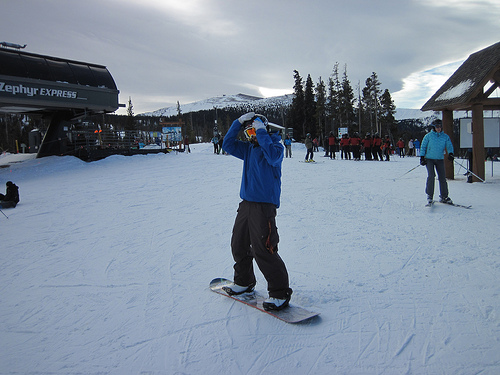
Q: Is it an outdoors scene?
A: Yes, it is outdoors.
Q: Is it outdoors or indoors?
A: It is outdoors.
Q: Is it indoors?
A: No, it is outdoors.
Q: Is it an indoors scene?
A: No, it is outdoors.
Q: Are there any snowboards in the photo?
A: Yes, there is a snowboard.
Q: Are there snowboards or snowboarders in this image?
A: Yes, there is a snowboard.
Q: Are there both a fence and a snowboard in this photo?
A: No, there is a snowboard but no fences.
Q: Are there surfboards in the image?
A: No, there are no surfboards.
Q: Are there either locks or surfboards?
A: No, there are no surfboards or locks.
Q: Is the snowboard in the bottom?
A: Yes, the snowboard is in the bottom of the image.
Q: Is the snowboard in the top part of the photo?
A: No, the snowboard is in the bottom of the image.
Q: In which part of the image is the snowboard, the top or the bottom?
A: The snowboard is in the bottom of the image.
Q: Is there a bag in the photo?
A: No, there are no bags.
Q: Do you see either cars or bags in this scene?
A: No, there are no bags or cars.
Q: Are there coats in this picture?
A: Yes, there is a coat.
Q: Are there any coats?
A: Yes, there is a coat.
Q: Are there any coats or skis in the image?
A: Yes, there is a coat.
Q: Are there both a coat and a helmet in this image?
A: Yes, there are both a coat and a helmet.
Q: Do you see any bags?
A: No, there are no bags.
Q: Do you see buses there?
A: Yes, there is a bus.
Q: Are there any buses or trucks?
A: Yes, there is a bus.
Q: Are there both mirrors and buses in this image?
A: No, there is a bus but no mirrors.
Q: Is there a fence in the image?
A: No, there are no fences.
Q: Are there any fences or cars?
A: No, there are no fences or cars.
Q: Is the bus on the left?
A: Yes, the bus is on the left of the image.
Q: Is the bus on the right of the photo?
A: No, the bus is on the left of the image.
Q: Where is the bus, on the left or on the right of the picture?
A: The bus is on the left of the image.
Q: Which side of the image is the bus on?
A: The bus is on the left of the image.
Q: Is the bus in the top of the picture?
A: Yes, the bus is in the top of the image.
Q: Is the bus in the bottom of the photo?
A: No, the bus is in the top of the image.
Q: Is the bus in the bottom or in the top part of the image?
A: The bus is in the top of the image.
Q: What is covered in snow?
A: The mountain is covered in snow.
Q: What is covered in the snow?
A: The mountain is covered in snow.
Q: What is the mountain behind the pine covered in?
A: The mountain is covered in snow.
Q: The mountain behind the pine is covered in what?
A: The mountain is covered in snow.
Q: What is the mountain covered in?
A: The mountain is covered in snow.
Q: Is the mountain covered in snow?
A: Yes, the mountain is covered in snow.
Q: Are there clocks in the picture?
A: No, there are no clocks.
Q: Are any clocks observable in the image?
A: No, there are no clocks.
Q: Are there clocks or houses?
A: No, there are no clocks or houses.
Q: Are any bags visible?
A: No, there are no bags.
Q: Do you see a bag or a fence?
A: No, there are no bags or fences.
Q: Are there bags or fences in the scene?
A: No, there are no bags or fences.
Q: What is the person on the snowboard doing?
A: The person is standing.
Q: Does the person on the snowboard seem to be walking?
A: No, the person is standing.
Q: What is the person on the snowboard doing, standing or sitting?
A: The person is standing.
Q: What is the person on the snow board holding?
A: The person is holding the helmet.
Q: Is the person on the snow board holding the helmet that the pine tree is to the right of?
A: Yes, the person is holding the helmet.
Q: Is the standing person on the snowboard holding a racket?
A: No, the person is holding the helmet.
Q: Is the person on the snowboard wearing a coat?
A: Yes, the person is wearing a coat.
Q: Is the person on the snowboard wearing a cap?
A: No, the person is wearing a coat.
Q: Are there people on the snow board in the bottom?
A: Yes, there is a person on the snow board.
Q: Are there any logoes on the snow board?
A: No, there is a person on the snow board.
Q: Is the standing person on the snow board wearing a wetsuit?
A: No, the person is wearing a helmet.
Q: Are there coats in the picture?
A: Yes, there is a coat.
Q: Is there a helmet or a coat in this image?
A: Yes, there is a coat.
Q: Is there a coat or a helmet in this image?
A: Yes, there is a coat.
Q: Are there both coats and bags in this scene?
A: No, there is a coat but no bags.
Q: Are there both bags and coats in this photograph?
A: No, there is a coat but no bags.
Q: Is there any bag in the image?
A: No, there are no bags.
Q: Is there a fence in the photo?
A: No, there are no fences.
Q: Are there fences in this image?
A: No, there are no fences.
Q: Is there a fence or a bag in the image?
A: No, there are no fences or bags.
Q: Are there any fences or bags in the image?
A: No, there are no fences or bags.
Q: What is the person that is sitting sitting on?
A: The person is sitting on the snow.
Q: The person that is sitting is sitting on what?
A: The person is sitting on the snow.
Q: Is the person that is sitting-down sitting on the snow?
A: Yes, the person is sitting on the snow.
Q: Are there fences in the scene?
A: No, there are no fences.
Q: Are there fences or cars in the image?
A: No, there are no fences or cars.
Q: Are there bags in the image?
A: No, there are no bags.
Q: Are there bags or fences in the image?
A: No, there are no bags or fences.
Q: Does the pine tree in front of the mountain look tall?
A: Yes, the pine is tall.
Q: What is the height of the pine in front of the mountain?
A: The pine tree is tall.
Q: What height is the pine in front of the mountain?
A: The pine tree is tall.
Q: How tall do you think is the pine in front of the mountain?
A: The pine tree is tall.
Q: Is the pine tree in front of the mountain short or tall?
A: The pine tree is tall.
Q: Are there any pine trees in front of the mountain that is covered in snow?
A: Yes, there is a pine tree in front of the mountain.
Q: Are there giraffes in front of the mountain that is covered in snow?
A: No, there is a pine tree in front of the mountain.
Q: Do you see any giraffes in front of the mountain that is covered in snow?
A: No, there is a pine tree in front of the mountain.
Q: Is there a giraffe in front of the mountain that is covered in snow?
A: No, there is a pine tree in front of the mountain.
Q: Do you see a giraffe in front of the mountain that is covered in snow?
A: No, there is a pine tree in front of the mountain.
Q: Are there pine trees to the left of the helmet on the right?
A: Yes, there is a pine tree to the left of the helmet.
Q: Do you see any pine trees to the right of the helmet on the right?
A: No, the pine tree is to the left of the helmet.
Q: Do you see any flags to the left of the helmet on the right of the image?
A: No, there is a pine tree to the left of the helmet.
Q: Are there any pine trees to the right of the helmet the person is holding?
A: Yes, there is a pine tree to the right of the helmet.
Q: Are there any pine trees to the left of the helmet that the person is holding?
A: No, the pine tree is to the right of the helmet.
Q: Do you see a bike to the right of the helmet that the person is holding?
A: No, there is a pine tree to the right of the helmet.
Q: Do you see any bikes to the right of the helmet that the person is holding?
A: No, there is a pine tree to the right of the helmet.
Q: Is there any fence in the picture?
A: No, there are no fences.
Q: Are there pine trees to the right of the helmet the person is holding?
A: Yes, there is a pine tree to the right of the helmet.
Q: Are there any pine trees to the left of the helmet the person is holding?
A: No, the pine tree is to the right of the helmet.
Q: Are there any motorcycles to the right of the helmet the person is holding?
A: No, there is a pine tree to the right of the helmet.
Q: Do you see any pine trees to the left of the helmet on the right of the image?
A: Yes, there is a pine tree to the left of the helmet.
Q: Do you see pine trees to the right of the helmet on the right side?
A: No, the pine tree is to the left of the helmet.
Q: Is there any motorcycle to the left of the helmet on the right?
A: No, there is a pine tree to the left of the helmet.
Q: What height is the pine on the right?
A: The pine tree is tall.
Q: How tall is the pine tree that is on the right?
A: The pine tree is tall.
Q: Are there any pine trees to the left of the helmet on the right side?
A: Yes, there is a pine tree to the left of the helmet.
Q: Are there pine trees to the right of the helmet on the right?
A: No, the pine tree is to the left of the helmet.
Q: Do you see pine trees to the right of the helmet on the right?
A: No, the pine tree is to the left of the helmet.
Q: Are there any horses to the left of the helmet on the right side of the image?
A: No, there is a pine tree to the left of the helmet.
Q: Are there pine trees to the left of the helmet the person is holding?
A: No, the pine tree is to the right of the helmet.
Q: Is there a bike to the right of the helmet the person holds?
A: No, there is a pine tree to the right of the helmet.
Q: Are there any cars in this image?
A: No, there are no cars.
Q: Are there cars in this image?
A: No, there are no cars.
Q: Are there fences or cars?
A: No, there are no cars or fences.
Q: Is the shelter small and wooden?
A: Yes, the shelter is small and wooden.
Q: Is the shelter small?
A: Yes, the shelter is small.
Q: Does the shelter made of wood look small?
A: Yes, the shelter is small.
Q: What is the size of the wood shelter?
A: The shelter is small.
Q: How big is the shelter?
A: The shelter is small.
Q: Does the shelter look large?
A: No, the shelter is small.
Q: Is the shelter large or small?
A: The shelter is small.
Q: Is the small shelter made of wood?
A: Yes, the shelter is made of wood.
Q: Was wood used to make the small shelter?
A: Yes, the shelter is made of wood.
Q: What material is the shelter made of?
A: The shelter is made of wood.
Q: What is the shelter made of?
A: The shelter is made of wood.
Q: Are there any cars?
A: No, there are no cars.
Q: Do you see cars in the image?
A: No, there are no cars.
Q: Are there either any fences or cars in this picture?
A: No, there are no cars or fences.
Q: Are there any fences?
A: No, there are no fences.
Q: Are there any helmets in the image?
A: Yes, there is a helmet.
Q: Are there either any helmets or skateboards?
A: Yes, there is a helmet.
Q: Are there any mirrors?
A: No, there are no mirrors.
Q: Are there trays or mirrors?
A: No, there are no mirrors or trays.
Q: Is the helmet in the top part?
A: Yes, the helmet is in the top of the image.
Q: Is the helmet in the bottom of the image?
A: No, the helmet is in the top of the image.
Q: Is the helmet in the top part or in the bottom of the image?
A: The helmet is in the top of the image.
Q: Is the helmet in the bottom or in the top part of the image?
A: The helmet is in the top of the image.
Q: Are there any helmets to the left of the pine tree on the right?
A: Yes, there is a helmet to the left of the pine tree.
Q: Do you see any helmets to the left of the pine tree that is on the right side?
A: Yes, there is a helmet to the left of the pine tree.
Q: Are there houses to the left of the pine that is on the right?
A: No, there is a helmet to the left of the pine.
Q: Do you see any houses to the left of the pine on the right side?
A: No, there is a helmet to the left of the pine.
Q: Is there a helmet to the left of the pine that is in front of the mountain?
A: Yes, there is a helmet to the left of the pine tree.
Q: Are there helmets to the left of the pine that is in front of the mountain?
A: Yes, there is a helmet to the left of the pine tree.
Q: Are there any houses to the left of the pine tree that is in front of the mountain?
A: No, there is a helmet to the left of the pine tree.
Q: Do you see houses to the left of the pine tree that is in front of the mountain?
A: No, there is a helmet to the left of the pine tree.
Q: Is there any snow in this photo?
A: Yes, there is snow.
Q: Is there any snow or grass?
A: Yes, there is snow.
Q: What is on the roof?
A: The snow is on the roof.